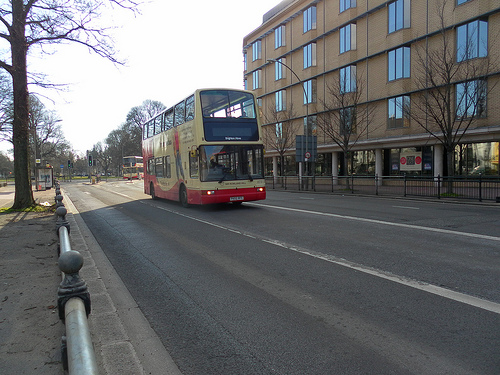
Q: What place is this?
A: It is a road.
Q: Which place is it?
A: It is a road.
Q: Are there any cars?
A: No, there are no cars.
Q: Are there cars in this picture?
A: No, there are no cars.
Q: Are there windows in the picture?
A: Yes, there is a window.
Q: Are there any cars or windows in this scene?
A: Yes, there is a window.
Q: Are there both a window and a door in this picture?
A: No, there is a window but no doors.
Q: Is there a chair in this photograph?
A: No, there are no chairs.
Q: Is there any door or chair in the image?
A: No, there are no chairs or doors.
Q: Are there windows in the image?
A: Yes, there is a window.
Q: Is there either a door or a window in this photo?
A: Yes, there is a window.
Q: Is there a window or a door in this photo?
A: Yes, there is a window.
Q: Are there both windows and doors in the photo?
A: No, there is a window but no doors.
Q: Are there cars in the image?
A: No, there are no cars.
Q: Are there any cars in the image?
A: No, there are no cars.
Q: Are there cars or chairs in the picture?
A: No, there are no cars or chairs.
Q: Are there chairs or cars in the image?
A: No, there are no cars or chairs.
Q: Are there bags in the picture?
A: No, there are no bags.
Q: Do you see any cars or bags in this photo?
A: No, there are no bags or cars.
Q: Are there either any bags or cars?
A: No, there are no bags or cars.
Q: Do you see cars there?
A: No, there are no cars.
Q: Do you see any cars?
A: No, there are no cars.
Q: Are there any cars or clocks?
A: No, there are no cars or clocks.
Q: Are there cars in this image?
A: No, there are no cars.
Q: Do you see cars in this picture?
A: No, there are no cars.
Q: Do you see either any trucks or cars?
A: No, there are no cars or trucks.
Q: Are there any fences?
A: Yes, there is a fence.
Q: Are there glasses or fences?
A: Yes, there is a fence.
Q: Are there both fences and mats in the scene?
A: No, there is a fence but no mats.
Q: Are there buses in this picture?
A: Yes, there is a bus.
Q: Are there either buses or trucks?
A: Yes, there is a bus.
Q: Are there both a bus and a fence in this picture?
A: Yes, there are both a bus and a fence.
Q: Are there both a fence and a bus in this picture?
A: Yes, there are both a bus and a fence.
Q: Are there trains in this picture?
A: No, there are no trains.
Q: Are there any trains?
A: No, there are no trains.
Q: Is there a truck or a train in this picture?
A: No, there are no trains or trucks.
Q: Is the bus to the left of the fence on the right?
A: Yes, the bus is to the left of the fence.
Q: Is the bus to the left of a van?
A: No, the bus is to the left of the fence.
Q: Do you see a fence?
A: Yes, there is a fence.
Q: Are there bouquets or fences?
A: Yes, there is a fence.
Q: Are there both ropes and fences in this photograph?
A: No, there is a fence but no ropes.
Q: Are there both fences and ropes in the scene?
A: No, there is a fence but no ropes.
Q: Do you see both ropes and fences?
A: No, there is a fence but no ropes.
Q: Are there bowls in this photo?
A: No, there are no bowls.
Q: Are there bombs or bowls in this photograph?
A: No, there are no bowls or bombs.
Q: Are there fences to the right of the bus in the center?
A: Yes, there is a fence to the right of the bus.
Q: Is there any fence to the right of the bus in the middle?
A: Yes, there is a fence to the right of the bus.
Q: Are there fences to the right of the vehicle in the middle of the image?
A: Yes, there is a fence to the right of the bus.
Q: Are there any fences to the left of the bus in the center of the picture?
A: No, the fence is to the right of the bus.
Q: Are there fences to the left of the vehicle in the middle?
A: No, the fence is to the right of the bus.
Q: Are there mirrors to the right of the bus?
A: No, there is a fence to the right of the bus.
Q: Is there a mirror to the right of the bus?
A: No, there is a fence to the right of the bus.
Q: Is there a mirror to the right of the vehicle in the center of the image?
A: No, there is a fence to the right of the bus.